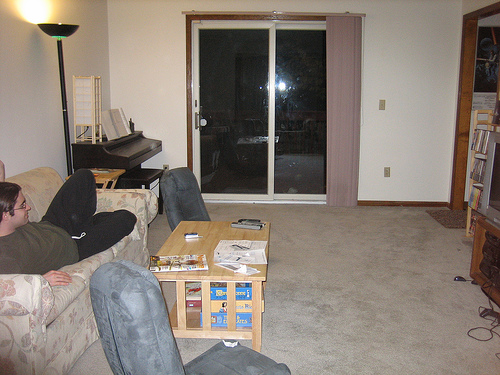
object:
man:
[0, 168, 138, 270]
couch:
[0, 166, 154, 374]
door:
[191, 21, 326, 195]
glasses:
[12, 201, 30, 209]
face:
[14, 192, 29, 226]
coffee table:
[152, 218, 271, 335]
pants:
[38, 170, 136, 257]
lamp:
[41, 22, 78, 176]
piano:
[72, 128, 165, 185]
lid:
[103, 134, 162, 158]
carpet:
[77, 193, 500, 374]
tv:
[476, 127, 500, 223]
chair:
[89, 259, 291, 374]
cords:
[478, 293, 498, 318]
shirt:
[0, 220, 77, 275]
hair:
[0, 183, 17, 220]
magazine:
[147, 253, 204, 272]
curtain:
[326, 18, 364, 208]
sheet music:
[99, 108, 127, 139]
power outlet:
[377, 99, 387, 111]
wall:
[107, 3, 461, 204]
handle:
[194, 112, 199, 129]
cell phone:
[184, 233, 197, 239]